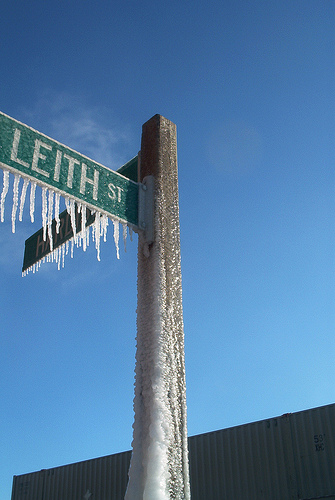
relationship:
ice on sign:
[3, 168, 135, 246] [2, 111, 138, 225]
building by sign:
[13, 403, 335, 499] [2, 111, 138, 225]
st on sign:
[107, 182, 128, 198] [2, 111, 138, 225]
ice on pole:
[128, 343, 166, 499] [138, 114, 194, 499]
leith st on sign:
[10, 133, 125, 199] [2, 111, 138, 225]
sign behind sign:
[20, 155, 146, 272] [2, 111, 138, 225]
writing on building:
[310, 430, 328, 455] [13, 403, 335, 499]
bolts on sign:
[140, 182, 148, 194] [2, 111, 138, 225]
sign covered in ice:
[2, 111, 138, 225] [3, 168, 135, 246]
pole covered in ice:
[138, 114, 194, 499] [128, 343, 166, 499]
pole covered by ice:
[138, 114, 194, 499] [128, 343, 166, 499]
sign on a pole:
[2, 111, 138, 225] [138, 114, 194, 499]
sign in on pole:
[2, 111, 138, 225] [138, 114, 194, 499]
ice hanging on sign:
[3, 168, 135, 246] [2, 111, 138, 225]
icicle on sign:
[12, 175, 17, 230] [2, 111, 138, 225]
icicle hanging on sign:
[12, 175, 17, 230] [2, 111, 138, 225]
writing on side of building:
[310, 430, 328, 455] [13, 403, 335, 499]